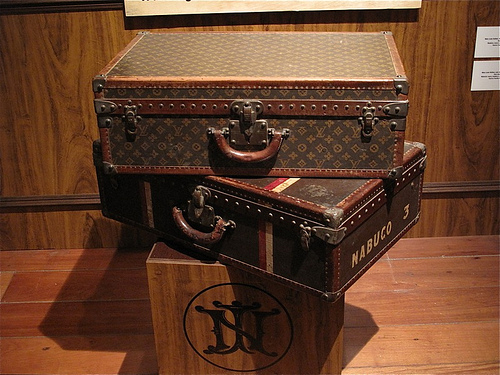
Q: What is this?
A: A pile of luggage.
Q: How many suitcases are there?
A: Two.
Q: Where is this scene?
A: In a room.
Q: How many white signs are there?
A: Two.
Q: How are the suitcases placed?
A: Stacked.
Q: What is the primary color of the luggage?
A: Brown.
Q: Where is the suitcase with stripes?
A: On the bottom.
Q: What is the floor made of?
A: Wood.